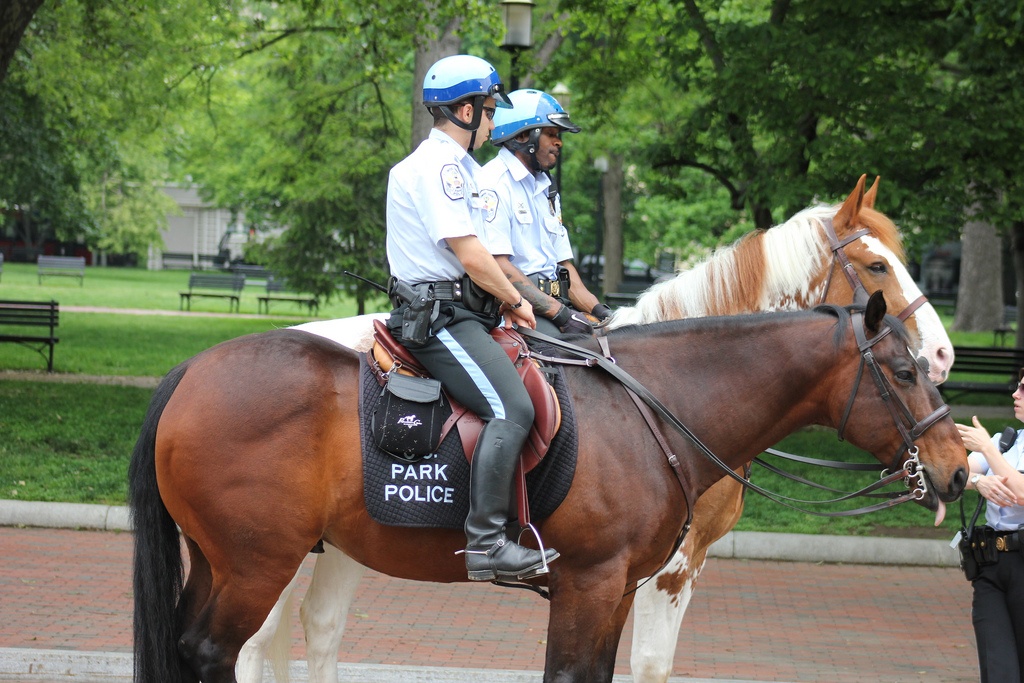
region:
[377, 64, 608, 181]
police have blue helmets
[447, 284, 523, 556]
men have black pants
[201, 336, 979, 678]
horse is dark brown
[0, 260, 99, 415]
black bench behind police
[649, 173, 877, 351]
brown and white mane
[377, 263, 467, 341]
black holster on police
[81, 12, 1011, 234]
green and leafy trees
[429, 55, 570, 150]
Safety helmets on heads.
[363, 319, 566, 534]
Horse saddle that has park police written on them.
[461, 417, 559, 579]
Black boot in stirrup.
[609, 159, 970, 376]
Brown and white horse head.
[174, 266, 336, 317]
Pair of park benches.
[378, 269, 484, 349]
Black belt and gun.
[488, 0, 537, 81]
White street lamp.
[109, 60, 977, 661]
Policemen on horses.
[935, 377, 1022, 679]
Lady police woman standing and talking.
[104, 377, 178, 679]
Bushy black horse tail.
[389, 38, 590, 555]
two men on horses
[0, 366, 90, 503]
green grass behind horses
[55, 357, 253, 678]
horse has black tail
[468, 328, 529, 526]
men have black and blue pants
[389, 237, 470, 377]
man has black holster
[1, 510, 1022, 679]
A brick paved road.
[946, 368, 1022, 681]
A person standing in front of the horses.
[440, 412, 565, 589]
A riding boot with a spur.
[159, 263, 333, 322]
Two benches next to each other in the park.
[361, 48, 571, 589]
White male police officer sitting on a horse.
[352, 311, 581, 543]
A saddle blanket that has words on it.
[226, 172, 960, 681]
A white and light-brown horse.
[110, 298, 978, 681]
A brown horse with a black tail.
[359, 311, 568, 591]
A brown leather saddle with stirrups.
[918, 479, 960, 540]
A horse tongue sticking out of its mouth.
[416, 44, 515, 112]
A blue and white protective helmet.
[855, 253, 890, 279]
A right horse eye.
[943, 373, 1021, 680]
A woman in black pants.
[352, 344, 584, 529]
A black horse saddle.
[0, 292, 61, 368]
A bench in a park.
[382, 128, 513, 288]
A police uniform shirt.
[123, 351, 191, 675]
A black horse tail.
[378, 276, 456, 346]
A gun in a holster.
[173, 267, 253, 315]
A park bench.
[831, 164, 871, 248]
A horse ear.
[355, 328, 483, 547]
park police saddle cover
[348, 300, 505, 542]
park police saddle cover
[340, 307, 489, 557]
park police saddle cover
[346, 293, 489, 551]
park police saddle cover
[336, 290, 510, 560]
park police saddle cover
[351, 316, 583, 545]
park police saddle cover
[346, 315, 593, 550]
park police saddle cover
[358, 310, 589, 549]
park police saddle cover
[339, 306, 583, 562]
park police saddle cover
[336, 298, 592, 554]
park police saddle cover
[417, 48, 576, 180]
police officers are wearing helmets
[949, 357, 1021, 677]
police officer standing in front of the horses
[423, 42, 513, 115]
helmet has a blue stripe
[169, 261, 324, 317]
two park benches along the sidewalk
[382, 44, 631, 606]
police officers on horses